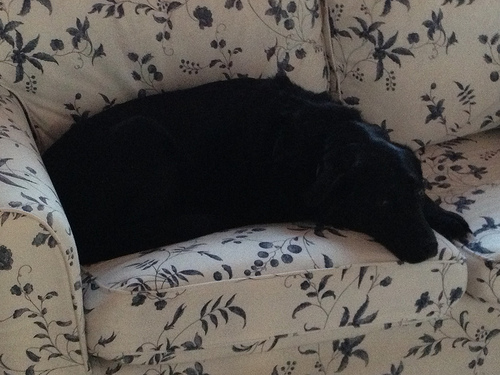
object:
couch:
[0, 0, 500, 374]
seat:
[0, 2, 468, 374]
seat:
[327, 0, 500, 373]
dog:
[43, 77, 471, 263]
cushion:
[78, 233, 472, 366]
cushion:
[335, 0, 500, 149]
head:
[324, 120, 439, 264]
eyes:
[373, 196, 393, 208]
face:
[370, 175, 443, 254]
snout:
[409, 237, 439, 254]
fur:
[86, 122, 145, 148]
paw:
[437, 208, 471, 241]